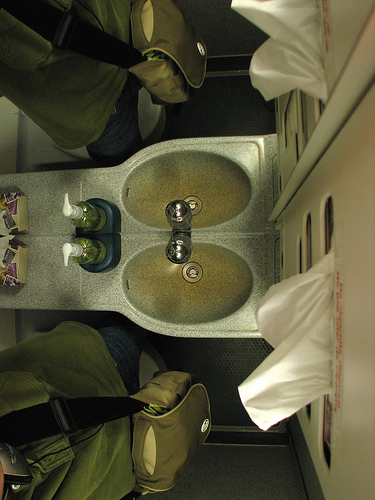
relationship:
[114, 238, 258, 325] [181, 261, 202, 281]
sink in drain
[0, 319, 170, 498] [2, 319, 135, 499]
person in shirt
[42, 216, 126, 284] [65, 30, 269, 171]
soap bottle in mirror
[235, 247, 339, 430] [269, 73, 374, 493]
tissue in container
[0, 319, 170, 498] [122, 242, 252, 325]
person in sink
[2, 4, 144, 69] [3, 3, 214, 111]
strap in bag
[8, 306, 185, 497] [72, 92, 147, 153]
he wears jeans